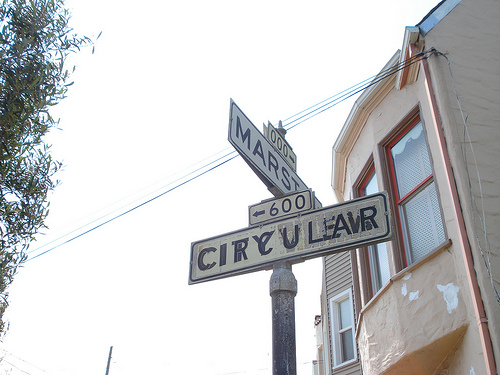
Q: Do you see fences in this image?
A: No, there are no fences.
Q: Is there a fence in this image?
A: No, there are no fences.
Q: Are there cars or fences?
A: No, there are no fences or cars.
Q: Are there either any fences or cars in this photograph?
A: No, there are no fences or cars.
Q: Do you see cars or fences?
A: No, there are no cars or fences.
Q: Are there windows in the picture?
A: Yes, there is a window.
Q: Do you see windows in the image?
A: Yes, there is a window.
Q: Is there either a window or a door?
A: Yes, there is a window.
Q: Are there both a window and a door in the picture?
A: No, there is a window but no doors.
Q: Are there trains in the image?
A: No, there are no trains.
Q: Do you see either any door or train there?
A: No, there are no trains or doors.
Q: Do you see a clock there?
A: No, there are no clocks.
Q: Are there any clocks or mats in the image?
A: No, there are no clocks or mats.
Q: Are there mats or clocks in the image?
A: No, there are no clocks or mats.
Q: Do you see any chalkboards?
A: No, there are no chalkboards.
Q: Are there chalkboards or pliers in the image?
A: No, there are no chalkboards or pliers.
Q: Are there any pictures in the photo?
A: No, there are no pictures.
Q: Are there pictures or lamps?
A: No, there are no pictures or lamps.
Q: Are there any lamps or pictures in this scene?
A: No, there are no pictures or lamps.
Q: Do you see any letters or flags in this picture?
A: Yes, there are letters.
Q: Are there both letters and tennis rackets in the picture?
A: No, there are letters but no rackets.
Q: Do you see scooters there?
A: No, there are no scooters.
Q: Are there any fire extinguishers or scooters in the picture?
A: No, there are no scooters or fire extinguishers.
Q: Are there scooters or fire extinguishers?
A: No, there are no scooters or fire extinguishers.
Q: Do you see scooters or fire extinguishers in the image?
A: No, there are no scooters or fire extinguishers.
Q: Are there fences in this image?
A: No, there are no fences.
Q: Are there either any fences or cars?
A: No, there are no fences or cars.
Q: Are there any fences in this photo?
A: No, there are no fences.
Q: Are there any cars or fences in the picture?
A: No, there are no fences or cars.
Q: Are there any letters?
A: Yes, there are letters.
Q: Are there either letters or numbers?
A: Yes, there are letters.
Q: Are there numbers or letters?
A: Yes, there are letters.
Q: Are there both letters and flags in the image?
A: No, there are letters but no flags.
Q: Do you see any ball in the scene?
A: No, there are no balls.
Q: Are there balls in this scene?
A: No, there are no balls.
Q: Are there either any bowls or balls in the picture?
A: No, there are no balls or bowls.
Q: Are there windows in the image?
A: Yes, there is a window.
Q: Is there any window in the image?
A: Yes, there is a window.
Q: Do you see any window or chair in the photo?
A: Yes, there is a window.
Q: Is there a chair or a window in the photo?
A: Yes, there is a window.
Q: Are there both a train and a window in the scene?
A: No, there is a window but no trains.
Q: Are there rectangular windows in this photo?
A: Yes, there is a rectangular window.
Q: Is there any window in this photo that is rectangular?
A: Yes, there is a window that is rectangular.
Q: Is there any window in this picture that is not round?
A: Yes, there is a rectangular window.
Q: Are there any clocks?
A: No, there are no clocks.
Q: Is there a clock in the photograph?
A: No, there are no clocks.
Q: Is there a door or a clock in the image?
A: No, there are no clocks or doors.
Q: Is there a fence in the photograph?
A: No, there are no fences.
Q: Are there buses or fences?
A: No, there are no fences or buses.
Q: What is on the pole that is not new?
A: The sign is on the pole.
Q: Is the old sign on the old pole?
A: Yes, the sign is on the pole.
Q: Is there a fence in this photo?
A: No, there are no fences.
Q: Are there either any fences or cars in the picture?
A: No, there are no fences or cars.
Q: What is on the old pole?
A: The sign is on the pole.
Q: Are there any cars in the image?
A: No, there are no cars.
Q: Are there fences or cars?
A: No, there are no cars or fences.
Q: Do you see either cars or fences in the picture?
A: No, there are no cars or fences.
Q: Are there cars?
A: No, there are no cars.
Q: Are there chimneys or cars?
A: No, there are no cars or chimneys.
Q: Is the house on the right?
A: Yes, the house is on the right of the image.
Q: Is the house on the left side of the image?
A: No, the house is on the right of the image.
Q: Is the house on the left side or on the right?
A: The house is on the right of the image.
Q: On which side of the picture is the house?
A: The house is on the right of the image.